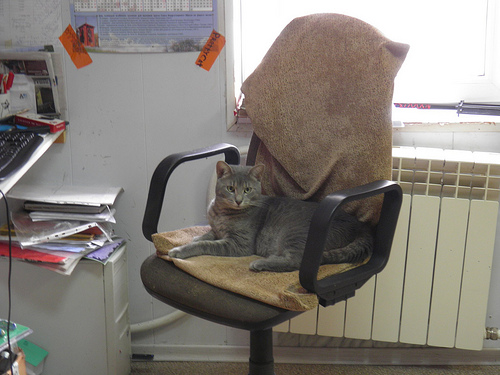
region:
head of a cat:
[198, 145, 283, 224]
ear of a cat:
[209, 157, 240, 184]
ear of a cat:
[243, 150, 282, 190]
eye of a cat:
[218, 178, 257, 202]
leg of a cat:
[176, 231, 228, 263]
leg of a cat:
[228, 240, 320, 281]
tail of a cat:
[296, 241, 408, 276]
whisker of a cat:
[243, 190, 267, 210]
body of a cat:
[231, 172, 408, 272]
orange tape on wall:
[194, 29, 224, 70]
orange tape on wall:
[58, 23, 92, 68]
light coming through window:
[231, 1, 499, 121]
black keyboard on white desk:
[0, 129, 43, 180]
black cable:
[1, 190, 17, 373]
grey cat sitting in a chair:
[164, 161, 374, 272]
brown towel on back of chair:
[240, 11, 408, 224]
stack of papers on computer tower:
[1, 182, 131, 373]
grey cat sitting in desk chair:
[140, 13, 410, 373]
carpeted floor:
[129, 360, 499, 373]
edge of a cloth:
[240, 275, 262, 302]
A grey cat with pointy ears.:
[169, 162, 374, 270]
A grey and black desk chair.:
[143, 11, 406, 374]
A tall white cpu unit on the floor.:
[1, 248, 132, 374]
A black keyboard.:
[2, 126, 44, 183]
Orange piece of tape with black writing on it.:
[195, 29, 227, 70]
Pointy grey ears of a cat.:
[214, 159, 265, 184]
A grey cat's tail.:
[318, 223, 373, 269]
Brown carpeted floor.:
[133, 357, 498, 374]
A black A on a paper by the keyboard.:
[16, 92, 26, 99]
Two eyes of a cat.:
[226, 184, 250, 194]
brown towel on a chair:
[254, 23, 406, 186]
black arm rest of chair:
[164, 143, 229, 177]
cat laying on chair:
[158, 160, 364, 279]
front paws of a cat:
[157, 230, 256, 272]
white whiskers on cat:
[241, 180, 266, 212]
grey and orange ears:
[241, 160, 271, 182]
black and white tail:
[315, 242, 369, 271]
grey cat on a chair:
[151, 161, 379, 286]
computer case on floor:
[0, 250, 133, 364]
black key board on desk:
[0, 127, 50, 169]